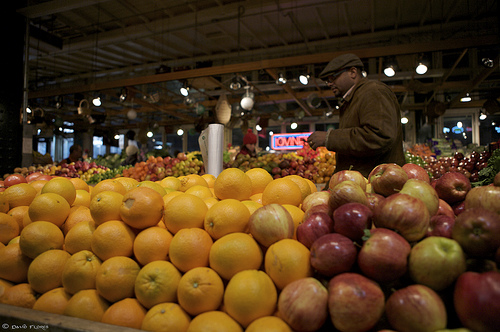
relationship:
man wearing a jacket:
[309, 52, 406, 177] [329, 79, 402, 171]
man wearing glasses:
[309, 52, 406, 177] [323, 71, 341, 83]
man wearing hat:
[309, 52, 406, 177] [318, 53, 361, 78]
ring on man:
[308, 139, 315, 145] [309, 52, 406, 177]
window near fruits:
[441, 115, 471, 148] [1, 165, 499, 331]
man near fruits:
[309, 52, 406, 177] [1, 165, 499, 331]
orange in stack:
[210, 233, 264, 280] [0, 169, 313, 331]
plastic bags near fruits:
[198, 123, 225, 176] [1, 165, 499, 331]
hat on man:
[318, 53, 361, 78] [309, 52, 406, 177]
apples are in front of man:
[282, 161, 500, 330] [309, 52, 406, 177]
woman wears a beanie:
[239, 129, 258, 158] [240, 128, 259, 143]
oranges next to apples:
[0, 169, 313, 331] [282, 161, 500, 330]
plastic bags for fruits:
[198, 123, 225, 176] [1, 165, 499, 331]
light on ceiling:
[92, 98, 101, 106] [23, 1, 499, 104]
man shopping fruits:
[309, 52, 406, 177] [1, 165, 499, 331]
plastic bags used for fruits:
[198, 123, 225, 176] [1, 165, 499, 331]